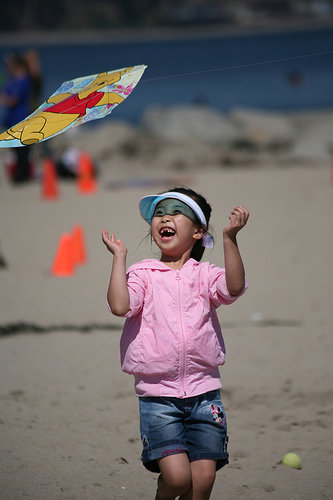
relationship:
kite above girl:
[1, 61, 159, 154] [102, 172, 255, 499]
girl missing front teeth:
[102, 172, 255, 499] [155, 224, 178, 241]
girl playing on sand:
[102, 172, 255, 499] [261, 176, 331, 318]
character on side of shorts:
[206, 395, 236, 431] [137, 394, 239, 469]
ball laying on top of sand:
[265, 448, 319, 484] [261, 176, 331, 318]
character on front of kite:
[63, 74, 130, 118] [1, 61, 159, 154]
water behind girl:
[149, 35, 292, 102] [102, 172, 255, 499]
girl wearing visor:
[102, 172, 255, 499] [137, 185, 214, 226]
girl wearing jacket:
[102, 172, 255, 499] [116, 257, 236, 395]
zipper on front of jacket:
[169, 269, 197, 404] [116, 257, 236, 395]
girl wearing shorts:
[102, 172, 255, 499] [137, 394, 239, 469]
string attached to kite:
[148, 39, 330, 91] [1, 61, 159, 154]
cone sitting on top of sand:
[32, 154, 64, 205] [261, 176, 331, 318]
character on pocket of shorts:
[206, 395, 236, 431] [137, 394, 239, 469]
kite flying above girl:
[1, 61, 159, 154] [102, 172, 255, 499]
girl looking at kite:
[102, 172, 255, 499] [1, 61, 159, 154]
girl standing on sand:
[102, 172, 255, 499] [261, 176, 331, 318]